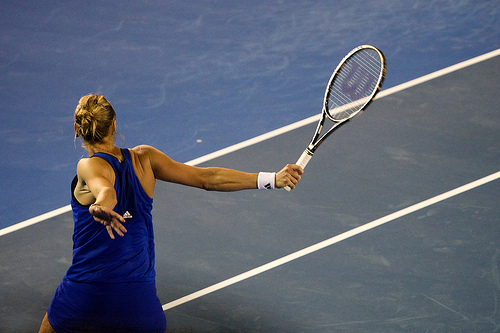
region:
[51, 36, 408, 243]
woman playing tennis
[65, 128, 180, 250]
player wearing sleeveless shirt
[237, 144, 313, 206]
player wearing white wrist guard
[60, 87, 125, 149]
player with tied hair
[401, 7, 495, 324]
floor is blue and gray with white lines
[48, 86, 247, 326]
player looking to the right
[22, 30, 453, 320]
player holds racket in right hand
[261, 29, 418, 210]
tennis racket with white handle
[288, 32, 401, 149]
racket has W inscription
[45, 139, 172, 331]
player wearing dark blue outfit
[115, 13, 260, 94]
The tennis court is blue.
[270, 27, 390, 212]
A tennis racket.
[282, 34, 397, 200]
The tennis racket is black and white.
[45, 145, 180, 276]
The person is wearing a blue top.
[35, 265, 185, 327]
The person is wearing shorts.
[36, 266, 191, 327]
The person is wearing blue shorts.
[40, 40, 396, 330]
The person is playing tennis.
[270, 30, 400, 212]
The person is holding a tennis racket.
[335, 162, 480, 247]
The ground has lines on it.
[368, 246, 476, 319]
The ground is gray.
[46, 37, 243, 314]
a woman in blue shirt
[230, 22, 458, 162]
the badminton rocket is white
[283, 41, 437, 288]
the badminton rocket is white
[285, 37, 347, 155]
the badminton rocket is white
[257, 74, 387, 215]
the badminton rocket is white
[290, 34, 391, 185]
the badminton rocket is white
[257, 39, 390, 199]
woman holding a tennis racket.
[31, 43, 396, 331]
the woman is playing tennis.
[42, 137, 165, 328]
woman wearing all blue.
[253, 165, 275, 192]
the wristband is white.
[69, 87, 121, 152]
the woman is blonde.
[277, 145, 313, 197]
the handle is white.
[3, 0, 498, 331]
the ground is blue.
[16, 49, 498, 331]
white lines on the ground.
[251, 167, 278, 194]
player wearing a sweatband.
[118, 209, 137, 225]
white logo on shirt.